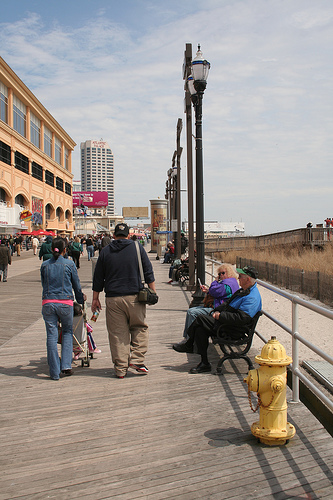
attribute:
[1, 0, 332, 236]
sky — blue, cascading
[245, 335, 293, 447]
fire hydrant — yellow, bright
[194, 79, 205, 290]
pole — black, metal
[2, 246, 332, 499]
boardwalk — wooden, wood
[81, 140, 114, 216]
building — tall, big, stone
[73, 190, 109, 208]
banner — pink, maroon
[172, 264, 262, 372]
man — elderly, carrying, older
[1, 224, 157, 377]
people — walking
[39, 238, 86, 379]
woman — pushing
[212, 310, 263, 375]
bench — black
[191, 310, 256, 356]
pants — black, blue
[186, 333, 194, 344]
socks — black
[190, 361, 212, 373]
shoes — blak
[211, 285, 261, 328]
coat — blue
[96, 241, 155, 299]
shirt — black, pink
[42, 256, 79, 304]
jacket — jean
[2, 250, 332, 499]
floor — wooden